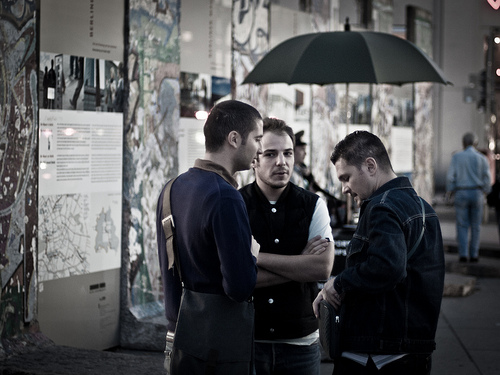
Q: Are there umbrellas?
A: Yes, there is an umbrella.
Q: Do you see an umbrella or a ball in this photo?
A: Yes, there is an umbrella.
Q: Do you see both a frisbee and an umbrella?
A: No, there is an umbrella but no frisbees.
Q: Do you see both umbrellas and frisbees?
A: No, there is an umbrella but no frisbees.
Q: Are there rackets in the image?
A: No, there are no rackets.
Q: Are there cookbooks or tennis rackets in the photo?
A: No, there are no tennis rackets or cookbooks.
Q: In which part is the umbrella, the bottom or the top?
A: The umbrella is in the top of the image.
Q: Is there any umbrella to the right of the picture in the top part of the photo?
A: Yes, there is an umbrella to the right of the picture.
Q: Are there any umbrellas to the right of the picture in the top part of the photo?
A: Yes, there is an umbrella to the right of the picture.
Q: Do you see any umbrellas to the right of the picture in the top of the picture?
A: Yes, there is an umbrella to the right of the picture.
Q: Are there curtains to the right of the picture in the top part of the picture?
A: No, there is an umbrella to the right of the picture.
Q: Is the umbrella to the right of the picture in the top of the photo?
A: Yes, the umbrella is to the right of the picture.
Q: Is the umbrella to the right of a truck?
A: No, the umbrella is to the right of the picture.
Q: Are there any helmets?
A: No, there are no helmets.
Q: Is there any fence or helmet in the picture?
A: No, there are no helmets or fences.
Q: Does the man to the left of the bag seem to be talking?
A: Yes, the man is talking.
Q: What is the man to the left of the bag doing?
A: The man is talking.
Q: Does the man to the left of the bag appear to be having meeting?
A: No, the man is talking.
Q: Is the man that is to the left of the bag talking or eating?
A: The man is talking.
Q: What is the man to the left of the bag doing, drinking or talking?
A: The man is talking.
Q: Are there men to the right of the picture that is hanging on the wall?
A: Yes, there is a man to the right of the picture.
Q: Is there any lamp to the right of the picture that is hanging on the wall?
A: No, there is a man to the right of the picture.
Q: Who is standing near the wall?
A: The man is standing near the wall.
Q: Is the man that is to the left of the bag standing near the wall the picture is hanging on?
A: Yes, the man is standing near the wall.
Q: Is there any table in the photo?
A: Yes, there is a table.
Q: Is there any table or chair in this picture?
A: Yes, there is a table.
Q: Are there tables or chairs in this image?
A: Yes, there is a table.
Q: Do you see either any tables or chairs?
A: Yes, there is a table.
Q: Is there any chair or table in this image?
A: Yes, there is a table.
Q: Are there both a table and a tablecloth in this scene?
A: No, there is a table but no tablecloths.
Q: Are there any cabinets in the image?
A: No, there are no cabinets.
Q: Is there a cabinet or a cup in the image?
A: No, there are no cabinets or cups.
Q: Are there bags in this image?
A: Yes, there is a bag.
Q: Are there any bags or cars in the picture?
A: Yes, there is a bag.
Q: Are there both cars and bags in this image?
A: No, there is a bag but no cars.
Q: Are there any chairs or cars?
A: No, there are no cars or chairs.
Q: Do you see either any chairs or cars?
A: No, there are no cars or chairs.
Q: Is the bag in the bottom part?
A: Yes, the bag is in the bottom of the image.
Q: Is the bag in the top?
A: No, the bag is in the bottom of the image.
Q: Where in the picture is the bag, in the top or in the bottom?
A: The bag is in the bottom of the image.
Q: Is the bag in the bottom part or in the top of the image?
A: The bag is in the bottom of the image.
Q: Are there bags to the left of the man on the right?
A: Yes, there is a bag to the left of the man.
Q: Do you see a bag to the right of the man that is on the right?
A: No, the bag is to the left of the man.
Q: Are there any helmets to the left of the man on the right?
A: No, there is a bag to the left of the man.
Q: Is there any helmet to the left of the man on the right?
A: No, there is a bag to the left of the man.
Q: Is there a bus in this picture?
A: No, there are no buses.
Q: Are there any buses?
A: No, there are no buses.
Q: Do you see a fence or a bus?
A: No, there are no buses or fences.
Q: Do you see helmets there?
A: No, there are no helmets.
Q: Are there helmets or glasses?
A: No, there are no helmets or glasses.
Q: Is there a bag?
A: Yes, there is a bag.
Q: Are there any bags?
A: Yes, there is a bag.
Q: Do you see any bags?
A: Yes, there is a bag.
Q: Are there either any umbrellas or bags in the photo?
A: Yes, there is a bag.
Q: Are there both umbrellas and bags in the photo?
A: Yes, there are both a bag and an umbrella.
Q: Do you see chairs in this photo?
A: No, there are no chairs.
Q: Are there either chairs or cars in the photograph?
A: No, there are no chairs or cars.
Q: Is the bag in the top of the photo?
A: No, the bag is in the bottom of the image.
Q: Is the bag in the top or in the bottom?
A: The bag is in the bottom of the image.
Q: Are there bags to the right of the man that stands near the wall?
A: Yes, there is a bag to the right of the man.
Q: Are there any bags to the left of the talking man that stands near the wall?
A: No, the bag is to the right of the man.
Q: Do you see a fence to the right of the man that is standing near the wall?
A: No, there is a bag to the right of the man.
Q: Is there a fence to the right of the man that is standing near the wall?
A: No, there is a bag to the right of the man.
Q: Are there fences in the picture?
A: No, there are no fences.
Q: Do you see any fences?
A: No, there are no fences.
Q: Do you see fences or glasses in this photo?
A: No, there are no fences or glasses.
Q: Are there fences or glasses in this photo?
A: No, there are no fences or glasses.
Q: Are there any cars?
A: No, there are no cars.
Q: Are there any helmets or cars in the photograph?
A: No, there are no cars or helmets.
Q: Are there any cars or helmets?
A: No, there are no cars or helmets.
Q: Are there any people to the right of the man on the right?
A: Yes, there is a person to the right of the man.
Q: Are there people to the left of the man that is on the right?
A: No, the person is to the right of the man.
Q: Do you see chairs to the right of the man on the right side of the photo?
A: No, there is a person to the right of the man.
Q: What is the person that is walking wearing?
A: The person is wearing a belt.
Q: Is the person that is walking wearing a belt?
A: Yes, the person is wearing a belt.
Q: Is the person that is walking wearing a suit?
A: No, the person is wearing a belt.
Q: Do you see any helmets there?
A: No, there are no helmets.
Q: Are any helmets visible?
A: No, there are no helmets.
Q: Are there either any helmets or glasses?
A: No, there are no helmets or glasses.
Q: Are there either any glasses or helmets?
A: No, there are no helmets or glasses.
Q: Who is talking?
A: The man is talking.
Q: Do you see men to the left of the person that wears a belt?
A: Yes, there is a man to the left of the person.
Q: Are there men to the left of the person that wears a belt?
A: Yes, there is a man to the left of the person.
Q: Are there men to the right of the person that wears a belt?
A: No, the man is to the left of the person.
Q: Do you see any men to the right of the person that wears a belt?
A: No, the man is to the left of the person.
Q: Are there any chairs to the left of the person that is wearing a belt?
A: No, there is a man to the left of the person.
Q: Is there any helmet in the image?
A: No, there are no helmets.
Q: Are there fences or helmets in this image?
A: No, there are no helmets or fences.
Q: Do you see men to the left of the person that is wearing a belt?
A: Yes, there is a man to the left of the person.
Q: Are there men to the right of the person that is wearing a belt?
A: No, the man is to the left of the person.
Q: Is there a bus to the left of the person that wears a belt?
A: No, there is a man to the left of the person.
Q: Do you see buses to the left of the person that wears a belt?
A: No, there is a man to the left of the person.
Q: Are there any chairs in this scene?
A: No, there are no chairs.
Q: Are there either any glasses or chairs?
A: No, there are no chairs or glasses.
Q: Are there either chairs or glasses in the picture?
A: No, there are no chairs or glasses.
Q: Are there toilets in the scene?
A: No, there are no toilets.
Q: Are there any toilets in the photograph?
A: No, there are no toilets.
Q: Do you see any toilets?
A: No, there are no toilets.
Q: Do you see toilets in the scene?
A: No, there are no toilets.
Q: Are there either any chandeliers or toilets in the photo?
A: No, there are no toilets or chandeliers.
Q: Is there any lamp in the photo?
A: No, there are no lamps.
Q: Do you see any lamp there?
A: No, there are no lamps.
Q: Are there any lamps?
A: No, there are no lamps.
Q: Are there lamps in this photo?
A: No, there are no lamps.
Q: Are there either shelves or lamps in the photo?
A: No, there are no lamps or shelves.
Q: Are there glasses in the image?
A: No, there are no glasses.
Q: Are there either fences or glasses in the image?
A: No, there are no glasses or fences.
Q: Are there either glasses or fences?
A: No, there are no glasses or fences.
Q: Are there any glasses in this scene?
A: No, there are no glasses.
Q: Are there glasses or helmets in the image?
A: No, there are no glasses or helmets.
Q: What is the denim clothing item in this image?
A: The clothing item is a jacket.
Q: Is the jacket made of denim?
A: Yes, the jacket is made of denim.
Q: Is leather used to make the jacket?
A: No, the jacket is made of denim.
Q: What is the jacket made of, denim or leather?
A: The jacket is made of denim.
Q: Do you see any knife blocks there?
A: No, there are no knife blocks.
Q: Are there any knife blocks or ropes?
A: No, there are no knife blocks or ropes.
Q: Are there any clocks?
A: No, there are no clocks.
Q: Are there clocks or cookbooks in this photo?
A: No, there are no clocks or cookbooks.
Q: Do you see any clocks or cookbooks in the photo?
A: No, there are no clocks or cookbooks.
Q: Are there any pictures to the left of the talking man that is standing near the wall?
A: Yes, there is a picture to the left of the man.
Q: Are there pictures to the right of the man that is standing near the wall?
A: No, the picture is to the left of the man.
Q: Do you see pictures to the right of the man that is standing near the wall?
A: No, the picture is to the left of the man.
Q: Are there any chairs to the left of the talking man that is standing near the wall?
A: No, there is a picture to the left of the man.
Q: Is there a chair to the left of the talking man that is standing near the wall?
A: No, there is a picture to the left of the man.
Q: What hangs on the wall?
A: The picture hangs on the wall.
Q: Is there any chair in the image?
A: No, there are no chairs.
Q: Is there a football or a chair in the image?
A: No, there are no chairs or footballs.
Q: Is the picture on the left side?
A: Yes, the picture is on the left of the image.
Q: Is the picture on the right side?
A: No, the picture is on the left of the image.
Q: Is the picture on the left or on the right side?
A: The picture is on the left of the image.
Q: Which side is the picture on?
A: The picture is on the left of the image.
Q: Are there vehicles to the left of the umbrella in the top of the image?
A: No, there is a picture to the left of the umbrella.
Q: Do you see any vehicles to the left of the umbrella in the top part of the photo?
A: No, there is a picture to the left of the umbrella.